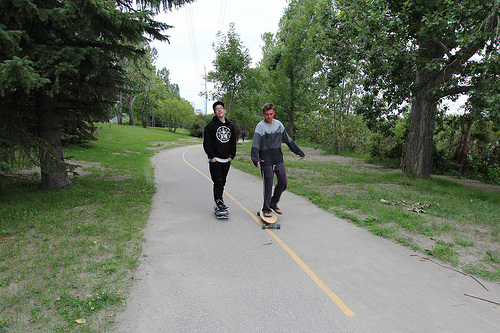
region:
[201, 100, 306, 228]
two young boys skateboarding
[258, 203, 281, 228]
skateboard young boy is on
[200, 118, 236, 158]
black sweat shirt with a white design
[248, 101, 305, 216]
young boy on a skateboard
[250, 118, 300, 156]
a black, dark gray and light gray sweater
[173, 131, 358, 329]
yellow strip down the middle of the road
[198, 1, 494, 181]
tall trees on the left side of the road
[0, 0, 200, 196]
one big tree on the right side of the road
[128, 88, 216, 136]
trees in the distance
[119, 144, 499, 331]
road the boys are skateboarding on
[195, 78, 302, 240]
they are skateboarding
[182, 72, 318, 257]
two guys skateboarding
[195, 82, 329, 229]
they are skateboarding on a path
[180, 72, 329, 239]
they are skating in a park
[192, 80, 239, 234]
he is dressed in all black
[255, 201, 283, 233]
this is a longboard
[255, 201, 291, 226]
he is wearing flip flops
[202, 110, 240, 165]
this hoodie is made by OBEY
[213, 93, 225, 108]
this is a black cap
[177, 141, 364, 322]
a yellow line down the road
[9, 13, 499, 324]
a scene outside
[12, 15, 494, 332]
a photo during the day time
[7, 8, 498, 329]
a scene at a park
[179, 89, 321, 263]
couple of people on walkway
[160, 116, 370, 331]
a yellow line on road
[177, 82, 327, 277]
two people on skateboards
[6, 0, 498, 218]
some green trees in the area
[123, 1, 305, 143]
a white sky in background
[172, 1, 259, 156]
power lines in the background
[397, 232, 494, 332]
limbs on road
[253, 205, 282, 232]
a skateboard guy is using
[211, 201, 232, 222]
skateboard the guy is using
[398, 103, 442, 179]
a trunk of the tree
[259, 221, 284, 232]
wheels of the skateboard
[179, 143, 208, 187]
a solid yellow line on road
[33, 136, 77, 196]
trunk of the tree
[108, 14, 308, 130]
tree lines in the background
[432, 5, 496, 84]
a branch of tree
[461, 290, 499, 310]
a stick on road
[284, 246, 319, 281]
yellow line on pavement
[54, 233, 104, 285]
a dirt and grassy area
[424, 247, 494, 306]
wooden sticks on the pavement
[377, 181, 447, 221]
a pile of wood in the grass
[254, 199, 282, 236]
someone stepping on a skateboard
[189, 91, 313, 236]
two boys on skateboards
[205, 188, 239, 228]
someone with both feet on a skateboard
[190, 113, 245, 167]
a boy wearing a dark sweatshirt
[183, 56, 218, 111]
a tall pole beyond the path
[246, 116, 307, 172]
a boy wearing a three color sweater